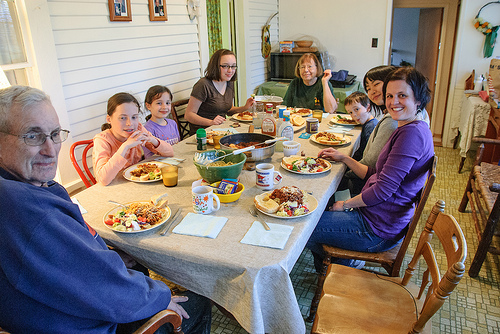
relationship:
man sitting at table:
[0, 85, 215, 334] [62, 86, 369, 332]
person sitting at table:
[340, 87, 381, 149] [62, 86, 369, 332]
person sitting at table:
[85, 88, 180, 186] [62, 86, 369, 332]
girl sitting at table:
[140, 85, 181, 160] [62, 86, 369, 332]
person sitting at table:
[183, 46, 244, 130] [62, 86, 369, 332]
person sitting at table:
[319, 67, 434, 257] [62, 86, 369, 332]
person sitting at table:
[361, 62, 391, 137] [62, 86, 369, 332]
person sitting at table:
[287, 41, 335, 106] [62, 86, 369, 332]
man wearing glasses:
[0, 85, 215, 334] [4, 125, 72, 145]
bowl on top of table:
[216, 130, 280, 162] [51, 98, 358, 332]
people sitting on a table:
[108, 60, 483, 272] [145, 124, 346, 288]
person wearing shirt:
[304, 68, 435, 274] [359, 114, 439, 237]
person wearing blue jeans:
[304, 68, 435, 274] [326, 203, 406, 256]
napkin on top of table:
[172, 212, 229, 239] [57, 102, 369, 301]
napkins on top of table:
[238, 217, 292, 252] [57, 102, 369, 301]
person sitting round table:
[304, 68, 435, 274] [63, 107, 363, 322]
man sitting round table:
[0, 85, 215, 334] [63, 107, 363, 322]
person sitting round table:
[94, 93, 174, 188] [63, 107, 363, 322]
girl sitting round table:
[140, 85, 181, 160] [63, 107, 363, 322]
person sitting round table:
[184, 48, 257, 136] [63, 107, 363, 322]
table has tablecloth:
[60, 100, 365, 275] [55, 104, 379, 329]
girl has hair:
[147, 85, 177, 145] [145, 83, 172, 95]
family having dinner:
[9, 38, 436, 331] [106, 197, 173, 232]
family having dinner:
[9, 38, 436, 331] [309, 127, 351, 146]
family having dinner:
[9, 38, 436, 331] [251, 187, 316, 222]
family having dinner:
[9, 38, 436, 331] [122, 155, 182, 182]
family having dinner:
[9, 38, 436, 331] [227, 104, 260, 125]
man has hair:
[4, 87, 205, 332] [4, 85, 45, 112]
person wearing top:
[304, 68, 435, 274] [359, 119, 435, 240]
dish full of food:
[102, 197, 169, 233] [105, 199, 164, 230]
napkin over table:
[175, 210, 226, 241] [63, 107, 363, 322]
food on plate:
[281, 151, 325, 170] [278, 151, 333, 175]